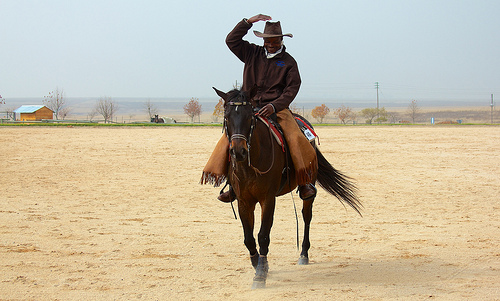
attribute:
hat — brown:
[261, 19, 289, 38]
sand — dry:
[415, 146, 461, 198]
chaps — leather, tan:
[285, 121, 309, 169]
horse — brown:
[212, 84, 279, 207]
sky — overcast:
[48, 18, 167, 63]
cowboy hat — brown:
[258, 25, 284, 38]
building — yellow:
[15, 101, 62, 124]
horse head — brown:
[212, 83, 260, 164]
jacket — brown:
[243, 59, 293, 88]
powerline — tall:
[366, 74, 383, 106]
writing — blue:
[273, 63, 288, 68]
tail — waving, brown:
[319, 162, 369, 222]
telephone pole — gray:
[482, 89, 500, 125]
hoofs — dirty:
[247, 250, 270, 292]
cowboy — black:
[235, 17, 300, 56]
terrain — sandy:
[108, 233, 173, 269]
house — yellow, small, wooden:
[17, 106, 57, 120]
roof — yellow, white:
[14, 106, 46, 114]